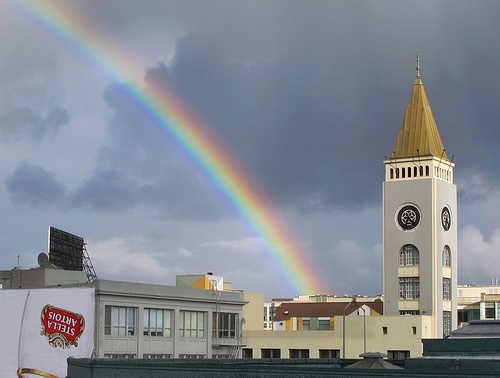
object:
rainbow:
[12, 0, 321, 296]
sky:
[2, 2, 499, 295]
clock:
[395, 201, 421, 233]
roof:
[385, 50, 451, 164]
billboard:
[37, 303, 87, 350]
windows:
[105, 305, 113, 336]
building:
[10, 280, 243, 360]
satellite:
[36, 252, 51, 267]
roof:
[13, 266, 248, 304]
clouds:
[243, 37, 382, 165]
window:
[399, 244, 419, 269]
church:
[383, 55, 459, 342]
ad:
[4, 288, 97, 376]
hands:
[403, 217, 408, 224]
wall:
[4, 290, 100, 377]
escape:
[214, 338, 245, 350]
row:
[105, 299, 250, 344]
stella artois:
[46, 311, 78, 335]